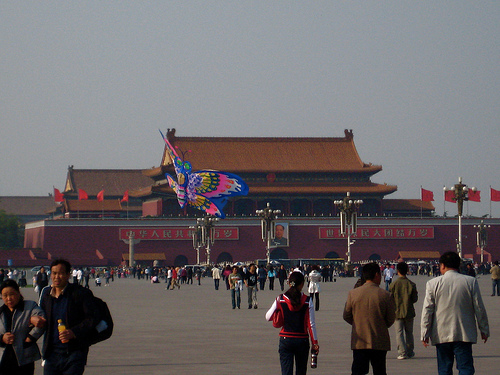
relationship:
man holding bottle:
[35, 259, 101, 373] [54, 318, 68, 344]